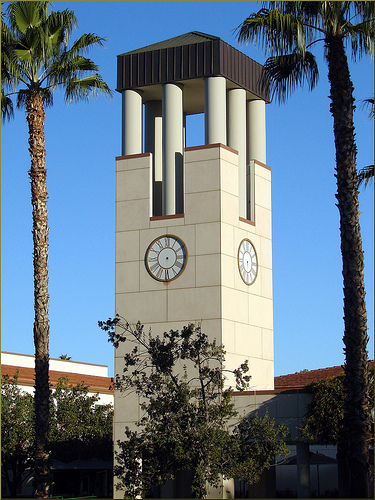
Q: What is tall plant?
A: Tree.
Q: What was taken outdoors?
A: Scene.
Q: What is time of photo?
A: In daytime.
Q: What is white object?
A: Tower.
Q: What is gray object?
A: Top.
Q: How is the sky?
A: Clear.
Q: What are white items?
A: Pillars.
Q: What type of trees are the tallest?
A: Palm trees.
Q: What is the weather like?
A: Sunny.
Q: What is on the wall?
A: Two clocks.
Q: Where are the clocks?
A: On the wall.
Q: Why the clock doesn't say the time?
A: It doesn't have hands.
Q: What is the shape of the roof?
A: Triangle.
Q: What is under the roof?
A: Tall and long columns.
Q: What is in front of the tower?
A: Trees.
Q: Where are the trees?
A: In front of the tower.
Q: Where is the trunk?
A: On a palm tree.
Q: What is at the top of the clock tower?
A: The roof.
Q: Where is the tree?
A: In front of the clock tower.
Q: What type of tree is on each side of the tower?
A: Palm tree.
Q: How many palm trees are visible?
A: Two.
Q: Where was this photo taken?
A: Outside during the daytime.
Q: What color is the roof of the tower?
A: Black.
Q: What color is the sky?
A: Blue.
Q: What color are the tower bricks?
A: Off-white.